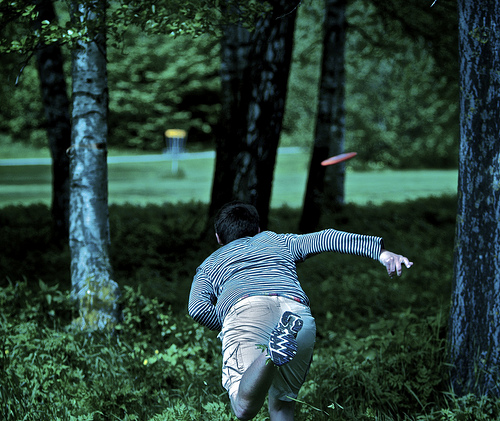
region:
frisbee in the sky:
[308, 137, 368, 179]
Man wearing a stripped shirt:
[189, 229, 386, 305]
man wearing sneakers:
[262, 303, 310, 365]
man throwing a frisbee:
[249, 200, 429, 287]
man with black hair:
[208, 202, 265, 240]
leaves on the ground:
[31, 275, 196, 405]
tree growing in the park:
[39, 46, 131, 326]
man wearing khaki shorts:
[218, 285, 333, 402]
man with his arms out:
[282, 210, 414, 280]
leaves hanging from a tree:
[118, 3, 250, 39]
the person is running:
[160, 185, 414, 419]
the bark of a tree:
[52, 25, 163, 352]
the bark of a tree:
[22, 26, 106, 297]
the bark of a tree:
[215, 2, 315, 266]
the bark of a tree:
[305, 13, 370, 280]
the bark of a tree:
[440, 0, 496, 411]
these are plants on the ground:
[131, 348, 213, 409]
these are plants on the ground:
[50, 345, 161, 412]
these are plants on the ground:
[350, 319, 414, 400]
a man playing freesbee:
[72, 83, 449, 418]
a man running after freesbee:
[125, 111, 440, 401]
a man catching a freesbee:
[69, 72, 497, 412]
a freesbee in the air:
[292, 103, 333, 170]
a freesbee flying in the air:
[323, 116, 375, 221]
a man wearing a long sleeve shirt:
[146, 170, 410, 414]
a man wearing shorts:
[203, 183, 383, 415]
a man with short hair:
[189, 168, 300, 384]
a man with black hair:
[178, 173, 328, 390]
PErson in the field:
[166, 176, 382, 403]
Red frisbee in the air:
[293, 139, 378, 176]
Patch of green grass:
[14, 357, 84, 419]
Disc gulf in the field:
[150, 110, 192, 189]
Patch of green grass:
[379, 355, 422, 409]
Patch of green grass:
[328, 361, 363, 411]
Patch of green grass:
[156, 364, 191, 419]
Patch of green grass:
[144, 284, 174, 364]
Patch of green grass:
[400, 191, 446, 262]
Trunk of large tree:
[411, 21, 498, 413]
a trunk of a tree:
[59, 8, 119, 330]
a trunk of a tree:
[301, 22, 363, 222]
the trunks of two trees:
[195, 24, 284, 209]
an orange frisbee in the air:
[317, 146, 364, 169]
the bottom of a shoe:
[263, 308, 308, 366]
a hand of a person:
[374, 239, 414, 281]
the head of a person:
[206, 200, 271, 247]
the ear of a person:
[211, 228, 223, 245]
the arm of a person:
[290, 225, 393, 260]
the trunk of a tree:
[446, 3, 496, 395]